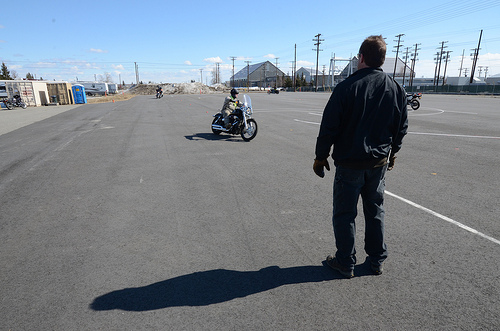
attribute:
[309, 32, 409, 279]
man — standing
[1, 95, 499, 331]
ground — paved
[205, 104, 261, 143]
motor cycle — black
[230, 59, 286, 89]
building — here, far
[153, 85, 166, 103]
bike — parked, stationary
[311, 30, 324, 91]
pole — erected, telephone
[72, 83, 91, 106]
portapotty — blue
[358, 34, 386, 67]
hair — brown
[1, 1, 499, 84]
sky — clear, cloudy